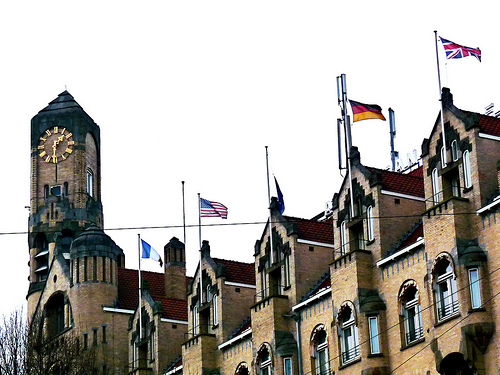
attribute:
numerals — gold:
[56, 136, 96, 156]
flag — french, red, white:
[194, 190, 233, 245]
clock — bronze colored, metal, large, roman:
[35, 124, 77, 167]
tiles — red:
[118, 269, 193, 317]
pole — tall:
[197, 191, 203, 252]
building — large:
[12, 80, 187, 374]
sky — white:
[7, 2, 487, 96]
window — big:
[35, 288, 81, 341]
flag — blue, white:
[132, 233, 167, 271]